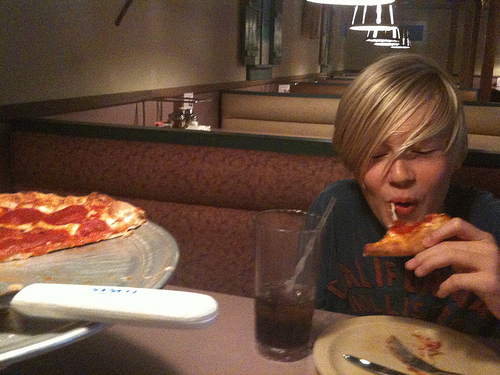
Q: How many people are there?
A: One.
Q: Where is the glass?
A: On the table.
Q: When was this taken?
A: Mealtime.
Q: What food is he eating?
A: Pizza.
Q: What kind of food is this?
A: Pizza.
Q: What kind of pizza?
A: Pepperoni.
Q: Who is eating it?
A: The kid.